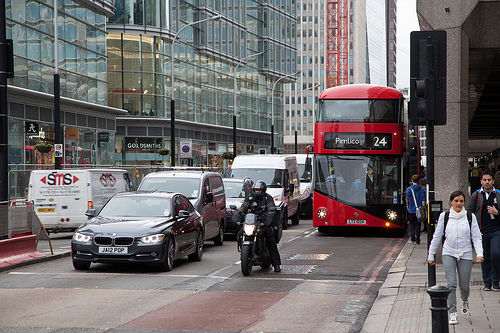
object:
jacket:
[427, 207, 486, 260]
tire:
[187, 227, 204, 263]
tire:
[159, 237, 175, 272]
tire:
[73, 257, 90, 271]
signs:
[177, 134, 195, 162]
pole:
[167, 96, 179, 163]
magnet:
[310, 79, 409, 235]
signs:
[160, 289, 246, 314]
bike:
[230, 204, 286, 273]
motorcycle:
[228, 203, 284, 277]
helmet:
[249, 179, 270, 200]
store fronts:
[8, 101, 267, 173]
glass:
[310, 150, 400, 209]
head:
[251, 181, 269, 200]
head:
[409, 173, 421, 185]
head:
[476, 172, 494, 191]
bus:
[313, 82, 410, 232]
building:
[0, 3, 299, 238]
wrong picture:
[83, 82, 379, 282]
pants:
[438, 251, 476, 315]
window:
[312, 154, 402, 203]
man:
[467, 173, 500, 290]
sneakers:
[448, 307, 459, 324]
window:
[318, 95, 405, 127]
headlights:
[386, 208, 396, 220]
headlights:
[315, 207, 326, 219]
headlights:
[135, 232, 167, 244]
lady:
[426, 190, 485, 324]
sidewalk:
[359, 230, 497, 332]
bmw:
[69, 188, 207, 273]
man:
[231, 182, 283, 273]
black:
[242, 189, 280, 266]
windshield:
[93, 195, 171, 217]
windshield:
[134, 176, 201, 193]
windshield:
[221, 180, 242, 197]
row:
[72, 147, 319, 274]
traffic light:
[408, 28, 446, 123]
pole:
[427, 130, 444, 292]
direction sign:
[180, 135, 193, 159]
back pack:
[434, 209, 449, 241]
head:
[446, 189, 465, 211]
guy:
[403, 170, 428, 248]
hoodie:
[405, 183, 426, 214]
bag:
[409, 186, 426, 221]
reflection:
[315, 155, 374, 201]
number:
[370, 132, 389, 149]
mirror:
[179, 209, 191, 219]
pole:
[52, 73, 62, 172]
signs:
[50, 143, 67, 160]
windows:
[57, 40, 116, 77]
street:
[3, 263, 364, 332]